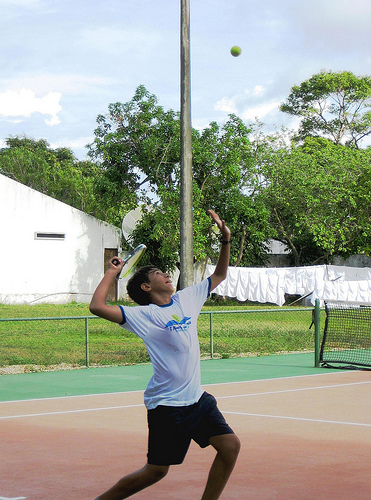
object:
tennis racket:
[110, 242, 147, 281]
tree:
[282, 66, 371, 150]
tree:
[266, 137, 371, 267]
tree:
[87, 83, 179, 194]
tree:
[0, 135, 128, 222]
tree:
[188, 122, 264, 267]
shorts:
[145, 388, 238, 470]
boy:
[86, 207, 242, 500]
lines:
[221, 385, 371, 427]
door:
[101, 244, 120, 303]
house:
[0, 165, 140, 305]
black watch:
[222, 238, 233, 245]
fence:
[0, 305, 321, 374]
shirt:
[118, 276, 215, 413]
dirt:
[0, 313, 315, 349]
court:
[0, 306, 369, 500]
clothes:
[284, 264, 314, 296]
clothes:
[265, 265, 287, 309]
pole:
[177, 0, 193, 294]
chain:
[10, 335, 36, 350]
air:
[0, 1, 371, 172]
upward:
[87, 195, 232, 336]